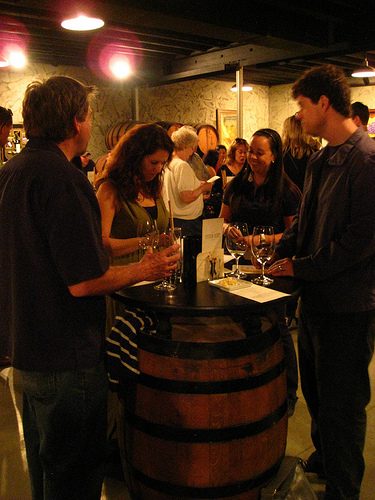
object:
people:
[165, 124, 204, 224]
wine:
[231, 250, 245, 260]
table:
[121, 270, 306, 318]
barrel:
[113, 322, 294, 496]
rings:
[149, 375, 261, 395]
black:
[115, 365, 122, 372]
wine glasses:
[251, 227, 277, 287]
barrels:
[105, 114, 140, 146]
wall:
[125, 86, 217, 118]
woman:
[102, 127, 172, 352]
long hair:
[109, 117, 174, 204]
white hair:
[175, 135, 180, 141]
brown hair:
[290, 69, 353, 102]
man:
[271, 51, 372, 500]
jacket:
[297, 134, 375, 283]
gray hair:
[186, 128, 197, 142]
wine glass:
[136, 221, 159, 263]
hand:
[143, 244, 181, 280]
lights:
[56, 9, 103, 38]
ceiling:
[160, 16, 297, 74]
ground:
[297, 400, 303, 414]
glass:
[226, 223, 249, 278]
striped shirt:
[102, 308, 155, 385]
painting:
[216, 107, 239, 146]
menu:
[207, 271, 292, 304]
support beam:
[235, 64, 245, 141]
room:
[2, 1, 373, 422]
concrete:
[3, 423, 18, 490]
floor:
[290, 432, 303, 453]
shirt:
[115, 187, 177, 260]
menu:
[206, 175, 220, 183]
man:
[0, 75, 125, 492]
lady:
[228, 129, 302, 255]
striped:
[114, 313, 135, 336]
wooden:
[147, 395, 159, 410]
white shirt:
[162, 160, 203, 221]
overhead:
[43, 55, 90, 79]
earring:
[272, 160, 274, 162]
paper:
[200, 217, 222, 252]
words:
[217, 232, 220, 236]